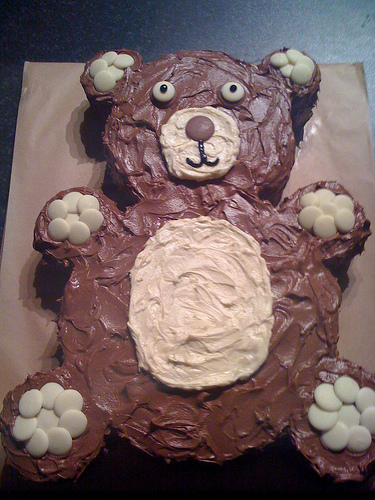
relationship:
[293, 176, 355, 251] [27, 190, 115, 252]
chocolate for paw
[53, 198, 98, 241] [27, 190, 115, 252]
pieces for paw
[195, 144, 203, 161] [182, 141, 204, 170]
line of frosting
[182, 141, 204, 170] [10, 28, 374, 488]
frosting of teddy bear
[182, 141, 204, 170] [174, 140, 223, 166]
frosting of mouth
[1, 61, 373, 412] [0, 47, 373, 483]
board with bear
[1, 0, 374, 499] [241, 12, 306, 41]
table with surface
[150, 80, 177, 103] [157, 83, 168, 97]
circular chip with black bead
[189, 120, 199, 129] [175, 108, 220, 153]
chocolate teddy bears nose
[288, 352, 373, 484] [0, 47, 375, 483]
bear's foot on bear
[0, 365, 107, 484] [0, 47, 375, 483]
bear's foot on bear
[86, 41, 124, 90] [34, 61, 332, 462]
ear on bear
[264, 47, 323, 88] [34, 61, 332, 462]
ear on bear